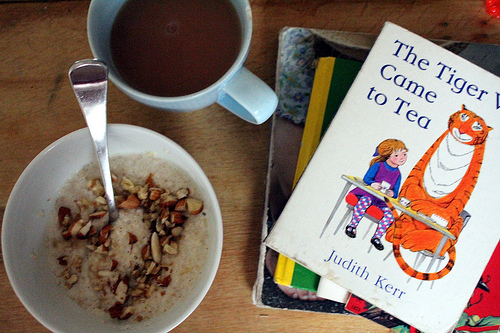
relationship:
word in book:
[364, 86, 433, 131] [259, 17, 499, 332]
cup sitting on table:
[79, 0, 277, 124] [2, 2, 497, 329]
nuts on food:
[133, 182, 183, 233] [38, 156, 207, 319]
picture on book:
[319, 99, 495, 290] [259, 17, 499, 332]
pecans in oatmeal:
[164, 244, 178, 255] [57, 154, 210, 325]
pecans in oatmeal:
[168, 225, 183, 237] [57, 154, 210, 325]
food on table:
[38, 156, 207, 319] [7, 4, 407, 331]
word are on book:
[364, 86, 433, 131] [281, 28, 498, 331]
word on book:
[378, 60, 444, 108] [281, 28, 498, 331]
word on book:
[358, 85, 433, 133] [290, 36, 498, 295]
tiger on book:
[387, 97, 472, 290] [281, 28, 498, 331]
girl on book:
[348, 128, 395, 268] [233, 43, 499, 331]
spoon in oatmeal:
[62, 52, 117, 210] [49, 179, 179, 319]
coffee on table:
[110, 0, 242, 97] [5, 8, 287, 318]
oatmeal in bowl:
[47, 151, 211, 317] [0, 122, 225, 332]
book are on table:
[261, 22, 498, 333] [2, 2, 497, 329]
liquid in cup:
[105, 2, 241, 99] [79, 3, 278, 125]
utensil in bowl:
[70, 70, 130, 211] [16, 149, 245, 311]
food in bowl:
[61, 172, 200, 295] [25, 125, 243, 331]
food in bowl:
[38, 156, 207, 319] [0, 122, 225, 332]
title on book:
[358, 42, 499, 133] [259, 17, 499, 332]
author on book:
[322, 249, 408, 298] [338, 50, 474, 181]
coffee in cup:
[124, 32, 213, 94] [68, 3, 330, 153]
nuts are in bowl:
[187, 199, 205, 215] [0, 169, 58, 281]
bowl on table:
[0, 122, 225, 332] [2, 2, 497, 329]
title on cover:
[363, 37, 500, 132] [264, 11, 499, 330]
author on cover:
[323, 247, 417, 302] [264, 11, 499, 330]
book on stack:
[261, 22, 498, 333] [247, 22, 499, 329]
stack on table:
[247, 22, 499, 329] [2, 2, 497, 329]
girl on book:
[343, 138, 407, 250] [305, 53, 491, 320]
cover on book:
[264, 21, 499, 330] [305, 53, 491, 320]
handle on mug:
[218, 71, 282, 141] [79, 1, 284, 143]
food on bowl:
[38, 156, 207, 319] [19, 106, 226, 330]